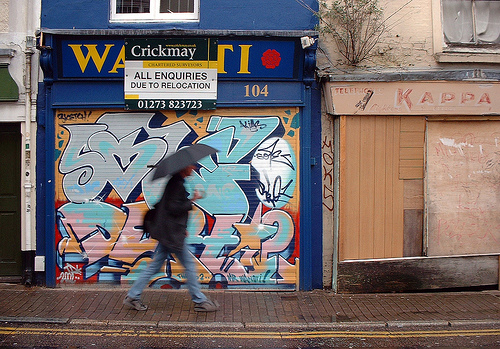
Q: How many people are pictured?
A: One.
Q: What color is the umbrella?
A: Black.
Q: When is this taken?
A: Daytime.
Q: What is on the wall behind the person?
A: Graffiti.